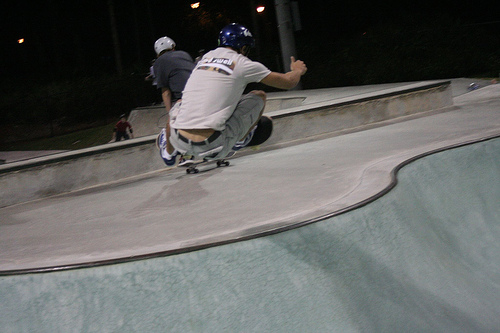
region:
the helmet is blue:
[211, 22, 259, 53]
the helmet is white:
[149, 35, 179, 56]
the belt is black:
[169, 127, 222, 144]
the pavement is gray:
[70, 183, 247, 237]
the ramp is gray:
[311, 235, 442, 322]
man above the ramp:
[177, 23, 457, 316]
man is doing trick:
[175, 10, 296, 170]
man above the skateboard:
[171, 30, 297, 174]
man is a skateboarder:
[178, 22, 298, 173]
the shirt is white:
[180, 42, 260, 145]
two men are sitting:
[148, 40, 305, 194]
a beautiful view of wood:
[41, 109, 498, 229]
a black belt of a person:
[165, 131, 220, 148]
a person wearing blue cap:
[216, 25, 272, 57]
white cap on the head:
[146, 39, 183, 56]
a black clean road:
[204, 171, 498, 325]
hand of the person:
[149, 91, 176, 111]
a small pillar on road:
[277, 2, 307, 77]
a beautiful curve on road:
[63, 149, 468, 276]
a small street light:
[230, 4, 282, 17]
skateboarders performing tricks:
[55, 16, 380, 196]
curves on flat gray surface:
[26, 121, 486, 293]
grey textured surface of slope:
[25, 213, 485, 319]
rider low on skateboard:
[145, 20, 320, 172]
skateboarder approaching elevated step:
[142, 21, 312, 181]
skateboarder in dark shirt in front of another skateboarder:
[145, 30, 210, 112]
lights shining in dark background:
[5, 11, 275, 51]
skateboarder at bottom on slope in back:
[80, 95, 141, 165]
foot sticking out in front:
[147, 110, 224, 170]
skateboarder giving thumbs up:
[185, 15, 317, 198]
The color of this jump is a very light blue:
[443, 231, 470, 292]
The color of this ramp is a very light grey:
[266, 174, 287, 214]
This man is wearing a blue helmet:
[220, 23, 250, 61]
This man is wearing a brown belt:
[172, 118, 224, 180]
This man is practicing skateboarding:
[217, 23, 284, 172]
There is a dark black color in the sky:
[413, 44, 422, 51]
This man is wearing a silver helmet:
[155, 32, 173, 64]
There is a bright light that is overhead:
[17, 27, 30, 49]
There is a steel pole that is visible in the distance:
[272, 25, 293, 52]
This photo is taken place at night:
[76, 16, 401, 280]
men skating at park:
[22, 17, 489, 301]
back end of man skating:
[167, 128, 254, 156]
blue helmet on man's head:
[210, 17, 260, 64]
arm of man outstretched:
[261, 25, 311, 97]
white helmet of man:
[111, 24, 191, 85]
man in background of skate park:
[91, 104, 138, 165]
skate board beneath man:
[14, 148, 259, 205]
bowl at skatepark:
[80, 170, 498, 307]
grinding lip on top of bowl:
[11, 155, 451, 285]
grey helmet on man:
[144, 31, 191, 49]